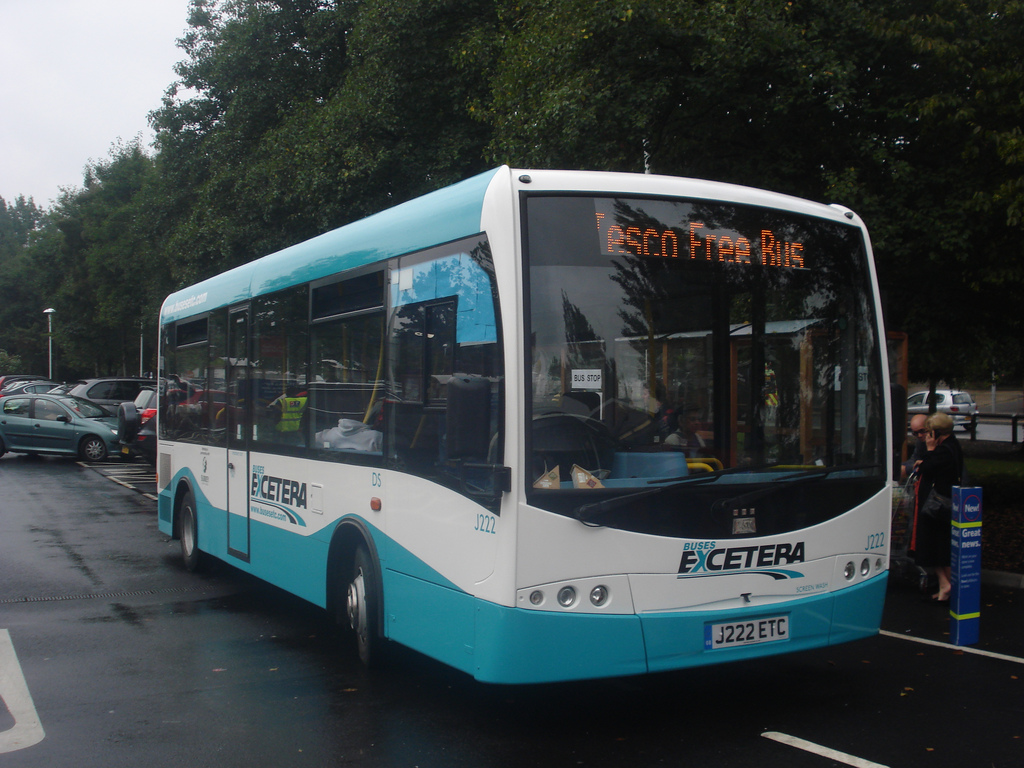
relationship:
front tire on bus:
[312, 520, 396, 701] [102, 142, 925, 703]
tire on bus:
[171, 487, 197, 573] [102, 142, 925, 703]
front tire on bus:
[329, 540, 389, 674] [102, 142, 925, 703]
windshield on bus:
[520, 197, 879, 495] [102, 142, 925, 703]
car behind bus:
[2, 392, 124, 463] [151, 165, 895, 679]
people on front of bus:
[899, 406, 969, 610] [151, 165, 895, 679]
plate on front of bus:
[700, 609, 796, 657] [102, 142, 925, 703]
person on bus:
[267, 383, 310, 453] [102, 142, 925, 703]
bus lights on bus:
[528, 557, 883, 608] [102, 142, 925, 703]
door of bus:
[206, 296, 263, 566] [102, 142, 925, 703]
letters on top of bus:
[575, 201, 813, 262] [77, 90, 902, 752]